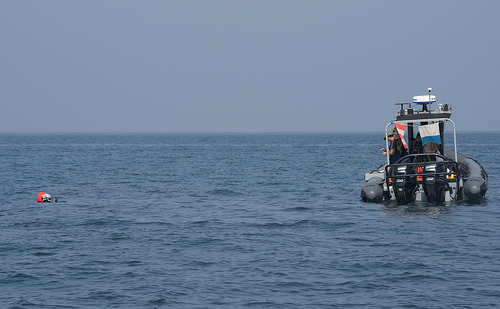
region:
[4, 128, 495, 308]
Large blue body of water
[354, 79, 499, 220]
Some type of boat in the water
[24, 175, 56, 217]
Orange ball in the middle of the water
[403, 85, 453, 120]
White antenna on top of the boat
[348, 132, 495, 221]
Black and grey flotation device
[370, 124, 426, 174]
Guy standing on boat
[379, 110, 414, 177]
Guy looking down at the water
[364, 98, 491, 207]
White pole on boat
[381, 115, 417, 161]
Orange and white flag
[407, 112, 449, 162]
Blue and white flag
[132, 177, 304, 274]
the water is blue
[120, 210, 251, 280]
the water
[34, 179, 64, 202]
object in the water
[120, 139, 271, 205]
the oceans water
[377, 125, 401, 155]
a person standing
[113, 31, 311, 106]
the sky is clear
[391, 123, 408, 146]
a flag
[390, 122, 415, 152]
flag is orange and white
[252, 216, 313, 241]
small waves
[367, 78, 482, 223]
boat in water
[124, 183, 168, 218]
white and green ocean waves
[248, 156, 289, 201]
white and green ocean waves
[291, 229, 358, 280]
white and green ocean waves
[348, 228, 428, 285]
white and green ocean waves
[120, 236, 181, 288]
white and green ocean waves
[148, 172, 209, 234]
white and green ocean waves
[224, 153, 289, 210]
white and green ocean waves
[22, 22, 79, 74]
white clouds in blue sky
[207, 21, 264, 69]
white clouds in blue sky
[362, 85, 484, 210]
boat on large body of water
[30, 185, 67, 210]
object floating in water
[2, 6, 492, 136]
clear blue sky over water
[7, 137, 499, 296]
large body of water with boat floating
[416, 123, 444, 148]
blue and white flag on boat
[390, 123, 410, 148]
orange and white flag on boat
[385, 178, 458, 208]
motors on the rear of boat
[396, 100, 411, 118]
radio tower on boat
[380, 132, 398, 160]
person standing on boat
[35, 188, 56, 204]
person with orange float in water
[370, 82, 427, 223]
boat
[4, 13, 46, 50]
white clouds in blue sky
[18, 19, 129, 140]
white clouds in blue sky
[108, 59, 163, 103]
white clouds in blue sky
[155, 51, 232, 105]
white clouds in blue sky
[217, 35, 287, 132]
white clouds in blue sky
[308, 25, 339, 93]
white clouds in blue sky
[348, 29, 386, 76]
white clouds in blue sky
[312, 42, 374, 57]
white clouds in blue sky